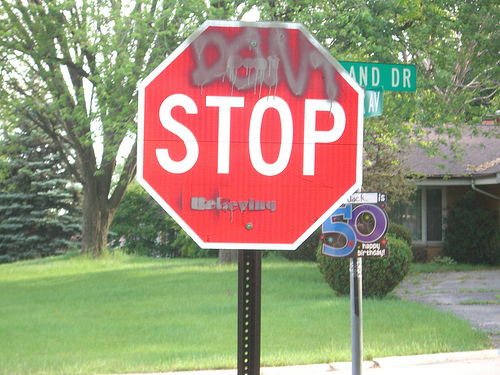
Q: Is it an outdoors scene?
A: Yes, it is outdoors.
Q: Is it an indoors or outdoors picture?
A: It is outdoors.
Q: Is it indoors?
A: No, it is outdoors.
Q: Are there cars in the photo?
A: No, there are no cars.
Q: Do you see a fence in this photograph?
A: No, there are no fences.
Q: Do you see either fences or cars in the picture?
A: No, there are no fences or cars.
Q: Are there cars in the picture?
A: No, there are no cars.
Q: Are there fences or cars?
A: No, there are no cars or fences.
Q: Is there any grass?
A: Yes, there is grass.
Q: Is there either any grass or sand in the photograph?
A: Yes, there is grass.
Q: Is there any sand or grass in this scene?
A: Yes, there is grass.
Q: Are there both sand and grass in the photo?
A: No, there is grass but no sand.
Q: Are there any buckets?
A: No, there are no buckets.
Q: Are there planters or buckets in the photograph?
A: No, there are no buckets or planters.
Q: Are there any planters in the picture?
A: No, there are no planters.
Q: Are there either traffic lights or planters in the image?
A: No, there are no planters or traffic lights.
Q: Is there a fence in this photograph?
A: No, there are no fences.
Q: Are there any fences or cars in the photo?
A: No, there are no fences or cars.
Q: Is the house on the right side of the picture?
A: Yes, the house is on the right of the image.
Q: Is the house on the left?
A: No, the house is on the right of the image.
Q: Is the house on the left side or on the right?
A: The house is on the right of the image.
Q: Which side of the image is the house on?
A: The house is on the right of the image.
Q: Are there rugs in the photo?
A: No, there are no rugs.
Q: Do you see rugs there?
A: No, there are no rugs.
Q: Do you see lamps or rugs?
A: No, there are no rugs or lamps.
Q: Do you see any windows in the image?
A: Yes, there is a window.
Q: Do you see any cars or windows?
A: Yes, there is a window.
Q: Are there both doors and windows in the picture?
A: No, there is a window but no doors.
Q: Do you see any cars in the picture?
A: No, there are no cars.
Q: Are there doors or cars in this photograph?
A: No, there are no cars or doors.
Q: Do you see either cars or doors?
A: No, there are no cars or doors.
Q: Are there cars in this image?
A: No, there are no cars.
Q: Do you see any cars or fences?
A: No, there are no cars or fences.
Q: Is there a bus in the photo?
A: No, there are no buses.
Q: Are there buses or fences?
A: No, there are no buses or fences.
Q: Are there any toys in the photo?
A: No, there are no toys.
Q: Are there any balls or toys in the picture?
A: No, there are no toys or balls.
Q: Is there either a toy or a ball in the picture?
A: No, there are no toys or balls.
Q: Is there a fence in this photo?
A: No, there are no fences.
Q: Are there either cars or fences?
A: No, there are no fences or cars.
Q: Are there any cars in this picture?
A: No, there are no cars.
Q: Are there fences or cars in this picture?
A: No, there are no cars or fences.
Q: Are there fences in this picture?
A: No, there are no fences.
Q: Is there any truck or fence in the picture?
A: No, there are no fences or trucks.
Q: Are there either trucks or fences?
A: No, there are no fences or trucks.